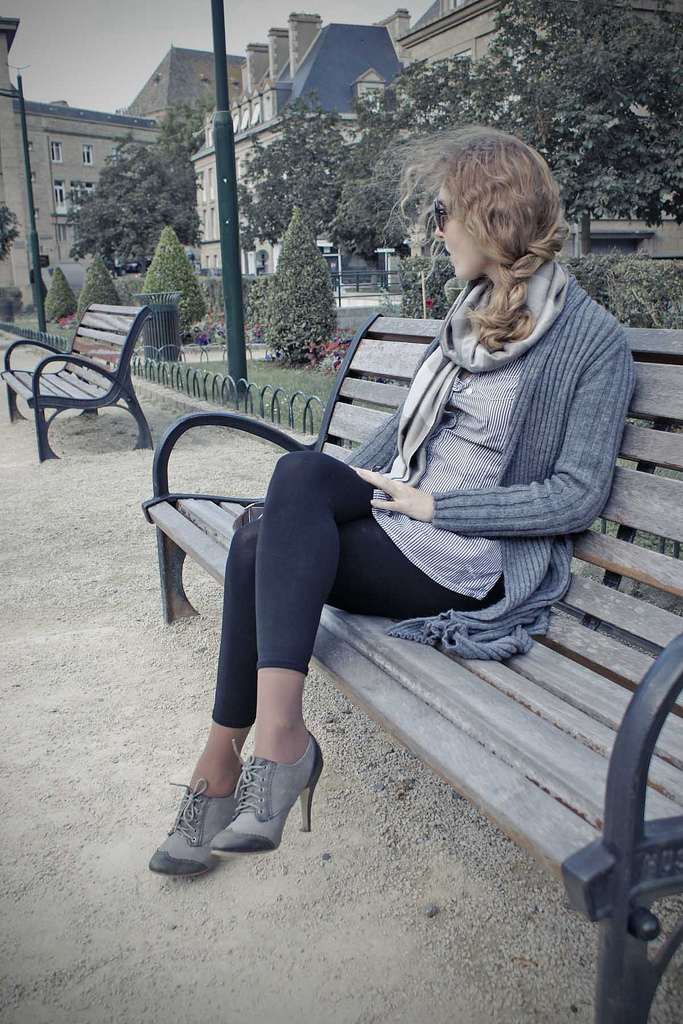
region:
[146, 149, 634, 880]
woman sitting on a bench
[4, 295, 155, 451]
a bench next to buildings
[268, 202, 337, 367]
tree next to a building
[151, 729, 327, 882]
heels on a woman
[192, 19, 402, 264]
building with a blue roof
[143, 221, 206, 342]
tree next to a garbage can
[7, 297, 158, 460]
bench placed in gravel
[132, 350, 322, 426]
a green rounded fence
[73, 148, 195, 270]
tree on the side of a building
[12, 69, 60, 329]
pole next to a building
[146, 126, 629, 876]
Woman sitting on a bench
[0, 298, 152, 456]
Empty park bench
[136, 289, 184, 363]
Garbage pail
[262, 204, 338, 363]
Tree along the sidewalk's edge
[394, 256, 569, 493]
Scarf around the woman's neck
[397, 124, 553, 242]
Woman's hair blowing in the wind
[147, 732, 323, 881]
High-heeled shoes on woman's feet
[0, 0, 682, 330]
Large building in the background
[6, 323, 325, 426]
Wrought iron fencing around the grass area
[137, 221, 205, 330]
Trimmed tree in the grassy area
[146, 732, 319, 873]
the high heel shoes are gray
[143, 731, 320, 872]
the shoe laces are gray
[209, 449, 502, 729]
the pair of leggings are black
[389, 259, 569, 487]
the scarf is gray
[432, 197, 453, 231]
the sunglasses are black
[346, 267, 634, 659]
the long sleeved sweater is gray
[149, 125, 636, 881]
the woman is sitting with her legs crossed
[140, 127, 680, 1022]
the woman crossing her legs and sitting on the bench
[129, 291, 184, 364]
the trash can is dark green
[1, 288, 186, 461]
the bench closest to the trash can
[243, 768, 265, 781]
lace on the shoe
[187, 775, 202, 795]
lace on the shoe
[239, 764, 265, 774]
lace on the shoe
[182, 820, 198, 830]
lace on the shoe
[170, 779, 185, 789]
lace on the shoe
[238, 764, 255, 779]
lace on the shoe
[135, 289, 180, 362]
Trashcan is green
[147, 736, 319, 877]
Grey high-heeled shoes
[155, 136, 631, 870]
Woman wearing gray cardigan looking off to the side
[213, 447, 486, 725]
Leggings are black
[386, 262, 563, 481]
scarf is gray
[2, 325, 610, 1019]
Path is dirt and gravel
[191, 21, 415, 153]
Roof is blue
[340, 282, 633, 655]
Sweater is long-sleeved and gray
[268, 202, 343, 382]
A tree in a city.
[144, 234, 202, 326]
A tree in a city.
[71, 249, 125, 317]
A tree in a city.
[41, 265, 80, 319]
A tree in a city.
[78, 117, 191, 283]
A tree in a city.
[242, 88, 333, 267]
A tree in a city.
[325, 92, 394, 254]
A tree in a city.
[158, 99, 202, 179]
A tree in a city.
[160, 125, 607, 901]
woman sitting on the bench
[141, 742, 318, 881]
gray lace up shoes with heels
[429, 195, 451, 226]
glasses the woman is wearing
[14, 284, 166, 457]
empty bench next to the woman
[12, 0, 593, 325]
buildings behind the benches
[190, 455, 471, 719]
black leggings the woman is wearing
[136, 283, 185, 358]
black trashcan behind the empty bench